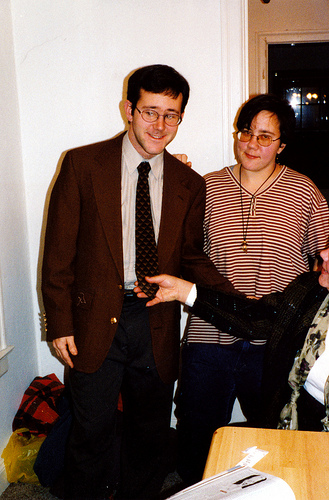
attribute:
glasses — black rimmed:
[122, 93, 188, 139]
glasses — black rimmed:
[127, 87, 186, 133]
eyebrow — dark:
[164, 106, 181, 116]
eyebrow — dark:
[237, 127, 254, 132]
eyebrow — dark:
[257, 129, 277, 137]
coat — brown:
[35, 128, 250, 378]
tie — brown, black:
[133, 160, 160, 301]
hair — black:
[124, 62, 190, 114]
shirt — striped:
[176, 165, 318, 350]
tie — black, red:
[136, 159, 161, 300]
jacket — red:
[34, 128, 249, 387]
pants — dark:
[61, 290, 169, 498]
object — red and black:
[9, 370, 65, 434]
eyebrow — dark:
[139, 104, 161, 109]